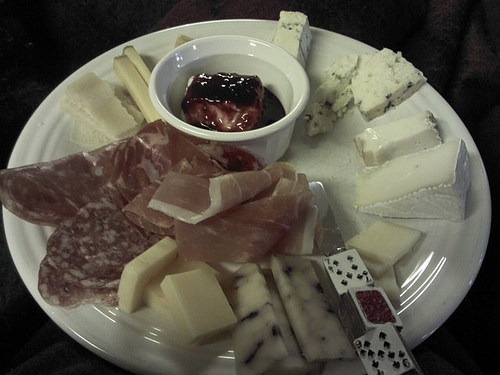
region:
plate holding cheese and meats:
[6, 10, 490, 372]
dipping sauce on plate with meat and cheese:
[146, 32, 308, 170]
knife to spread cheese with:
[299, 176, 417, 371]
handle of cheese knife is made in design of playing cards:
[318, 248, 413, 373]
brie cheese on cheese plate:
[360, 140, 468, 216]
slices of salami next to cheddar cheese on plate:
[36, 200, 148, 307]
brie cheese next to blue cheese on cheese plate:
[357, 111, 446, 163]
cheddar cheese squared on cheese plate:
[163, 272, 237, 333]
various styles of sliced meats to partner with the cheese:
[2, 128, 291, 258]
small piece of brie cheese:
[361, 109, 438, 152]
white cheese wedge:
[350, 135, 472, 225]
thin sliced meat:
[126, 162, 313, 260]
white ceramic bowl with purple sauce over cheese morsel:
[150, 33, 312, 167]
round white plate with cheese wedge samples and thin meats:
[3, 10, 492, 373]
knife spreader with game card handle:
[306, 181, 418, 374]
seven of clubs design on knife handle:
[318, 248, 377, 295]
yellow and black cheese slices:
[230, 251, 356, 373]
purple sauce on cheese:
[196, 72, 253, 103]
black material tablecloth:
[426, 3, 499, 78]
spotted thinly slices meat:
[51, 207, 148, 305]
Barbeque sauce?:
[155, 50, 312, 131]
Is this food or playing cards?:
[311, 220, 419, 369]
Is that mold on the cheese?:
[215, 251, 297, 373]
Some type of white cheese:
[110, 236, 232, 350]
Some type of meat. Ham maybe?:
[158, 178, 274, 234]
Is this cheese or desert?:
[340, 150, 488, 216]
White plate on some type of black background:
[30, 47, 77, 130]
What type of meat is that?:
[26, 163, 131, 275]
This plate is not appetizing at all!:
[62, 29, 499, 314]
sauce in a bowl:
[161, 55, 301, 142]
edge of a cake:
[403, 181, 466, 217]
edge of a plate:
[428, 274, 469, 345]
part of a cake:
[186, 288, 243, 330]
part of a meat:
[66, 265, 114, 316]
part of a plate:
[422, 252, 462, 289]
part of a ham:
[186, 190, 251, 230]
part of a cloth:
[28, 337, 59, 362]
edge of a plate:
[188, 216, 218, 223]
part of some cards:
[326, 255, 349, 277]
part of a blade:
[313, 199, 339, 251]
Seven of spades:
[322, 248, 374, 291]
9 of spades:
[343, 325, 410, 374]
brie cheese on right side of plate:
[352, 113, 476, 224]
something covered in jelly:
[180, 67, 270, 129]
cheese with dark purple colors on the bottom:
[227, 263, 336, 370]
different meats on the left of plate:
[16, 146, 279, 279]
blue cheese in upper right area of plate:
[277, 10, 414, 112]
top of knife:
[314, 175, 346, 255]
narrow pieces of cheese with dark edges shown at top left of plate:
[113, 39, 157, 120]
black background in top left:
[9, 9, 80, 59]